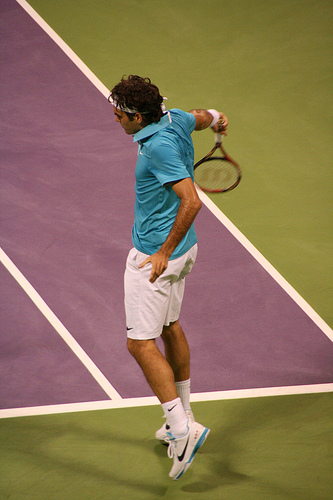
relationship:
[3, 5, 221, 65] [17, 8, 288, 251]
multiple colors on court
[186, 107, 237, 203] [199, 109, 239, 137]
racket in hand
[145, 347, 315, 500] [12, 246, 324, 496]
shadow on ground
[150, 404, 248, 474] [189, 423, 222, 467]
shoe has blue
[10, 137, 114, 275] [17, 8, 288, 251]
purple on court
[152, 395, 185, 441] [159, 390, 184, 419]
sock has checkmark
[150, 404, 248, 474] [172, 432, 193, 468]
shoe has checkmark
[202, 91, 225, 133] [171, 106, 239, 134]
sweatband on arm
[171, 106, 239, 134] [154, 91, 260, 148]
arm in motion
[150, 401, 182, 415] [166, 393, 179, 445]
logo on socks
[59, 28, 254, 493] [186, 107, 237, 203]
player swinging racket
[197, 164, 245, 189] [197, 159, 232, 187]
logo on netting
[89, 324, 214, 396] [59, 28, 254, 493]
legs on person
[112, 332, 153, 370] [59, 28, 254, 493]
knee of person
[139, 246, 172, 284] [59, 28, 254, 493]
hand on person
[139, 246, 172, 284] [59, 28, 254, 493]
hand of person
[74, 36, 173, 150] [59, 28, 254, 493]
head on person